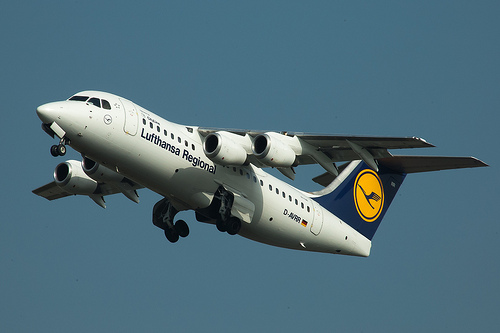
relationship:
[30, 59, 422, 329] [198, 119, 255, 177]
plane has engine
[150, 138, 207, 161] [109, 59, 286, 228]
writing on body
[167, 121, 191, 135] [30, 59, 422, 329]
window on plane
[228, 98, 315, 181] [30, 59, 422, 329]
jet on plane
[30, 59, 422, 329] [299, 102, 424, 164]
plane has wing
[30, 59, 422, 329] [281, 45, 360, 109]
plane in air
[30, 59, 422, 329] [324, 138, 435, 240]
plane has tail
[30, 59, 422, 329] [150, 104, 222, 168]
plane has letter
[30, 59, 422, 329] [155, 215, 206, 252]
plane has wheel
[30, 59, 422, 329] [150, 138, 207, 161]
plane has writing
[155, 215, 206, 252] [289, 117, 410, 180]
wheel above flap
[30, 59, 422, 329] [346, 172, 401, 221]
plane has flag